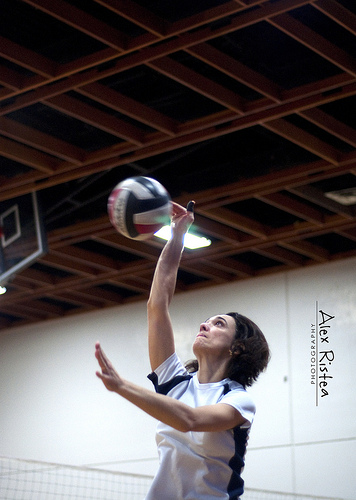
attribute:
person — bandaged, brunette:
[82, 170, 296, 499]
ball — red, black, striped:
[98, 168, 180, 247]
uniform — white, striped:
[124, 353, 262, 499]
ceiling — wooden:
[1, 0, 355, 303]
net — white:
[1, 447, 224, 498]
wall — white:
[2, 310, 354, 496]